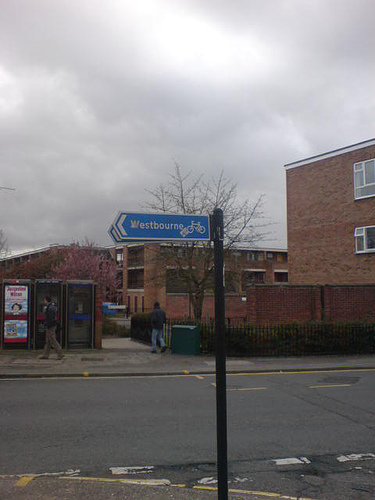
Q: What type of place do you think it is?
A: It is a street.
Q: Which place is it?
A: It is a street.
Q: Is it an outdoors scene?
A: Yes, it is outdoors.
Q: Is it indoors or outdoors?
A: It is outdoors.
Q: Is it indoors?
A: No, it is outdoors.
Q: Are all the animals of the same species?
A: Yes, all the animals are cows.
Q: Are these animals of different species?
A: No, all the animals are cows.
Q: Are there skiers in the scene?
A: No, there are no skiers.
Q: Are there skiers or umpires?
A: No, there are no skiers or umpires.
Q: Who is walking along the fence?
A: The guy is walking along the fence.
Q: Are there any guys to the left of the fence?
A: Yes, there is a guy to the left of the fence.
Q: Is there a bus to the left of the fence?
A: No, there is a guy to the left of the fence.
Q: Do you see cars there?
A: No, there are no cars.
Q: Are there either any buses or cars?
A: No, there are no cars or buses.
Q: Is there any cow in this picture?
A: Yes, there are cows.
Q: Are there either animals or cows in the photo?
A: Yes, there are cows.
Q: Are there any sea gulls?
A: No, there are no sea gulls.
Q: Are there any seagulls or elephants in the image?
A: No, there are no seagulls or elephants.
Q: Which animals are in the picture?
A: The animals are cows.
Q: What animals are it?
A: The animals are cows.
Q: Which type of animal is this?
A: These are cows.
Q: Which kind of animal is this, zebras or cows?
A: These are cows.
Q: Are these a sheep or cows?
A: These are cows.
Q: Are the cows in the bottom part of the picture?
A: Yes, the cows are in the bottom of the image.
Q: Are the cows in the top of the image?
A: No, the cows are in the bottom of the image.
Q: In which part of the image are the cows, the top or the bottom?
A: The cows are in the bottom of the image.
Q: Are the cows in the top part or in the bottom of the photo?
A: The cows are in the bottom of the image.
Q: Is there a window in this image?
A: Yes, there is a window.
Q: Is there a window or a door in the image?
A: Yes, there is a window.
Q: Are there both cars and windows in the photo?
A: No, there is a window but no cars.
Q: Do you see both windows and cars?
A: No, there is a window but no cars.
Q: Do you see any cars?
A: No, there are no cars.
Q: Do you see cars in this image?
A: No, there are no cars.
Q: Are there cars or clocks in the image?
A: No, there are no cars or clocks.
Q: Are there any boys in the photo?
A: No, there are no boys.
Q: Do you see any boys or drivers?
A: No, there are no boys or drivers.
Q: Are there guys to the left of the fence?
A: Yes, there is a guy to the left of the fence.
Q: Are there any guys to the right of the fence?
A: No, the guy is to the left of the fence.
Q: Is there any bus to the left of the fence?
A: No, there is a guy to the left of the fence.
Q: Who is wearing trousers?
A: The guy is wearing trousers.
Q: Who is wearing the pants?
A: The guy is wearing trousers.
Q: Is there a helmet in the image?
A: No, there are no helmets.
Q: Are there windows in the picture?
A: Yes, there is a window.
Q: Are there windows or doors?
A: Yes, there is a window.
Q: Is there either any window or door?
A: Yes, there is a window.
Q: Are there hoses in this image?
A: No, there are no hoses.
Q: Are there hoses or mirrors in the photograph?
A: No, there are no hoses or mirrors.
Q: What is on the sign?
A: The letter is on the sign.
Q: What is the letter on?
A: The letter is on the sign.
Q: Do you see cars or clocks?
A: No, there are no cars or clocks.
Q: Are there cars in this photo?
A: No, there are no cars.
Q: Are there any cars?
A: No, there are no cars.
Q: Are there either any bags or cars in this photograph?
A: No, there are no cars or bags.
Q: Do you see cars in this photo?
A: No, there are no cars.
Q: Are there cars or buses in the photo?
A: No, there are no cars or buses.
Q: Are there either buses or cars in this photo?
A: No, there are no cars or buses.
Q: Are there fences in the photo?
A: Yes, there is a fence.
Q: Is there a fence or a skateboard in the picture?
A: Yes, there is a fence.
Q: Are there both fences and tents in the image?
A: No, there is a fence but no tents.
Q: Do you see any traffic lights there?
A: No, there are no traffic lights.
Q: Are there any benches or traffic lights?
A: No, there are no traffic lights or benches.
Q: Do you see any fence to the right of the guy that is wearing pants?
A: Yes, there is a fence to the right of the guy.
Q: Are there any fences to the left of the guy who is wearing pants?
A: No, the fence is to the right of the guy.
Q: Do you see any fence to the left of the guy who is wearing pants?
A: No, the fence is to the right of the guy.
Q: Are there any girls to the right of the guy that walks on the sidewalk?
A: No, there is a fence to the right of the guy.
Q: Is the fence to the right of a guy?
A: Yes, the fence is to the right of a guy.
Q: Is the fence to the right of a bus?
A: No, the fence is to the right of a guy.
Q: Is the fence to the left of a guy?
A: No, the fence is to the right of a guy.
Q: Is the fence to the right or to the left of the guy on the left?
A: The fence is to the right of the guy.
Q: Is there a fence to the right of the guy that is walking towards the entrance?
A: Yes, there is a fence to the right of the guy.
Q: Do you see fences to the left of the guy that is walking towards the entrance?
A: No, the fence is to the right of the guy.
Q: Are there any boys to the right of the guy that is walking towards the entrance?
A: No, there is a fence to the right of the guy.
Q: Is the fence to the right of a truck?
A: No, the fence is to the right of a guy.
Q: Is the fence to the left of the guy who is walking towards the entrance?
A: No, the fence is to the right of the guy.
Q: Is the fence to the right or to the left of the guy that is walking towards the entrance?
A: The fence is to the right of the guy.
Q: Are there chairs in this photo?
A: No, there are no chairs.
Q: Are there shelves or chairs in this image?
A: No, there are no chairs or shelves.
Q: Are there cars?
A: No, there are no cars.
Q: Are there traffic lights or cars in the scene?
A: No, there are no cars or traffic lights.